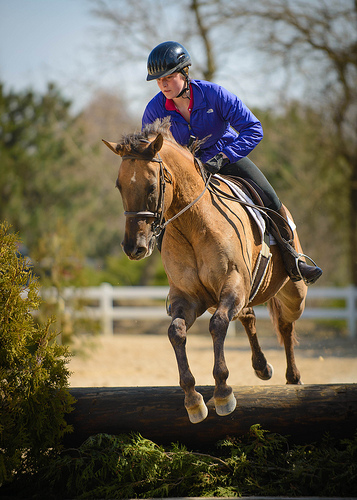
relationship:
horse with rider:
[127, 148, 258, 312] [178, 37, 333, 246]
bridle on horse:
[151, 171, 223, 232] [127, 148, 258, 312]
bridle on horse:
[151, 173, 212, 238] [127, 148, 258, 312]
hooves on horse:
[153, 370, 255, 421] [127, 148, 258, 312]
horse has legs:
[127, 148, 258, 312] [163, 303, 355, 376]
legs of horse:
[163, 303, 355, 376] [127, 148, 258, 312]